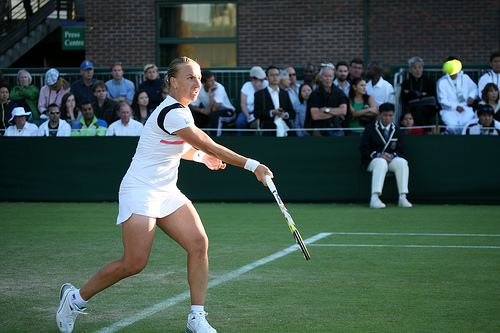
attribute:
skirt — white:
[112, 182, 192, 223]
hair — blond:
[167, 50, 199, 84]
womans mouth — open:
[184, 90, 202, 94]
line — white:
[119, 204, 332, 329]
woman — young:
[51, 47, 278, 330]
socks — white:
[188, 303, 204, 315]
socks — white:
[82, 282, 85, 301]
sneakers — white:
[186, 315, 213, 330]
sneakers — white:
[52, 279, 76, 326]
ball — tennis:
[442, 42, 468, 82]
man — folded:
[306, 59, 352, 136]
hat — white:
[11, 105, 30, 123]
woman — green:
[350, 71, 374, 120]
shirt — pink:
[39, 79, 69, 114]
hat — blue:
[75, 58, 97, 73]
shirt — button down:
[101, 76, 141, 100]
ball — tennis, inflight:
[444, 46, 474, 93]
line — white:
[95, 215, 328, 329]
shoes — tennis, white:
[42, 285, 217, 331]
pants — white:
[368, 151, 416, 198]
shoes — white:
[366, 193, 421, 213]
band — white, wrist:
[234, 149, 258, 173]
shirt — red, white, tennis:
[122, 90, 194, 192]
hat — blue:
[78, 58, 102, 78]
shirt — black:
[298, 83, 358, 125]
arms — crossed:
[306, 101, 361, 121]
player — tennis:
[50, 55, 299, 327]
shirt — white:
[128, 95, 206, 200]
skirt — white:
[107, 168, 207, 231]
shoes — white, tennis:
[53, 279, 223, 330]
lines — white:
[105, 225, 498, 324]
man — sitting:
[361, 98, 428, 210]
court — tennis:
[4, 191, 497, 328]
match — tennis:
[14, 47, 498, 329]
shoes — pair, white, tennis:
[45, 273, 223, 331]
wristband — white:
[236, 157, 268, 178]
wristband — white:
[189, 146, 207, 166]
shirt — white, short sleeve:
[124, 93, 220, 189]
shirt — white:
[124, 93, 197, 193]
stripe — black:
[155, 100, 185, 136]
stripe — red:
[159, 138, 185, 147]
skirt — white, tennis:
[114, 170, 191, 225]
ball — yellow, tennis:
[442, 58, 464, 75]